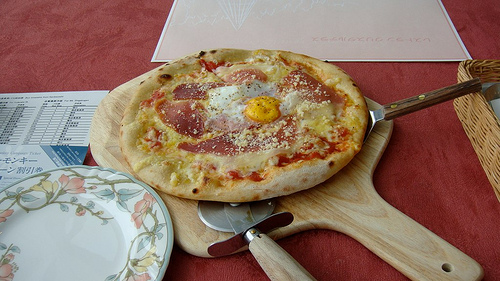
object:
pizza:
[120, 49, 369, 203]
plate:
[0, 161, 173, 279]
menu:
[1, 89, 99, 189]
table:
[2, 2, 496, 278]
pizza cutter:
[196, 196, 323, 281]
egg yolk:
[246, 97, 279, 121]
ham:
[164, 99, 208, 134]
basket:
[453, 60, 499, 203]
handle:
[247, 234, 317, 280]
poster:
[150, 1, 472, 63]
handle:
[336, 194, 489, 279]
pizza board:
[96, 72, 494, 280]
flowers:
[32, 174, 89, 205]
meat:
[282, 70, 339, 105]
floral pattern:
[119, 192, 179, 270]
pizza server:
[355, 79, 485, 145]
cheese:
[233, 125, 281, 140]